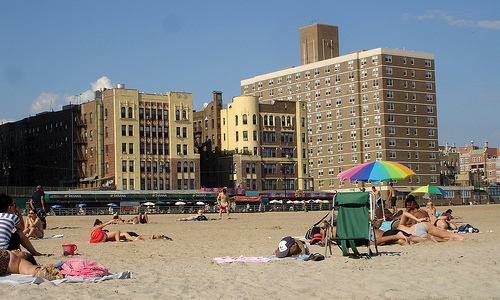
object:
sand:
[174, 271, 238, 299]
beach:
[0, 204, 500, 300]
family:
[308, 191, 464, 247]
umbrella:
[334, 159, 420, 186]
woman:
[1, 247, 65, 282]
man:
[26, 182, 49, 229]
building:
[0, 86, 206, 194]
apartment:
[238, 22, 451, 189]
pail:
[58, 242, 80, 258]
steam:
[78, 92, 84, 103]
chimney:
[93, 86, 110, 100]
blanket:
[52, 258, 111, 280]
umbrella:
[142, 201, 156, 206]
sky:
[128, 2, 278, 69]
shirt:
[0, 212, 22, 251]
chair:
[322, 190, 383, 257]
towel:
[209, 253, 277, 265]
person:
[174, 214, 209, 221]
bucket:
[60, 241, 80, 256]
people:
[386, 181, 399, 214]